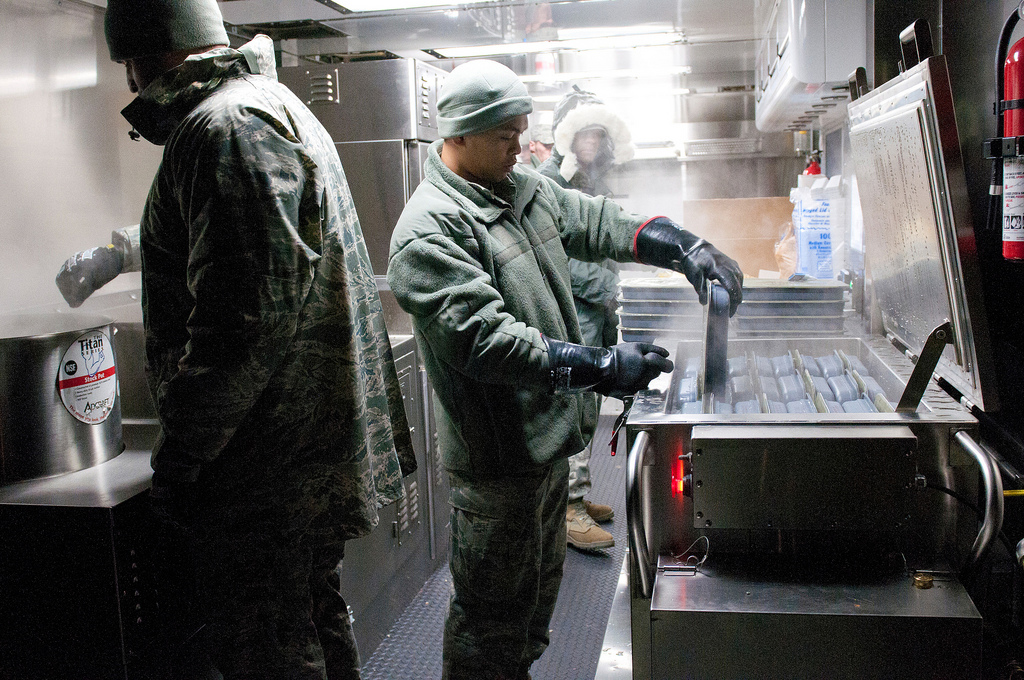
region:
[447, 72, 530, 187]
the head of a man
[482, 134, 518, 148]
the eyes of a man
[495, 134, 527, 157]
the nose of a man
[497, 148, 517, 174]
the mouth of a man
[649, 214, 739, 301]
the left hand of a man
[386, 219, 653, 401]
the right arm of a man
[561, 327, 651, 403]
the right hand of a man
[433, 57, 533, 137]
a man wearing a hat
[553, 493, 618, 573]
a man wearing brown boots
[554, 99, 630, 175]
a man wearing a coat hood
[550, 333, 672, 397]
a man wearing black gloves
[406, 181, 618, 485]
a man wearing a green sweetshirt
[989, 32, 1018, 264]
a red fire exstiguisher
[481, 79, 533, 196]
a man looking down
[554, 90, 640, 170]
white fake fur around a hood of a coat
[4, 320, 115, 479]
a silver metal pot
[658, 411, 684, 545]
Red light on front of machine.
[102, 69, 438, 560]
Large camoflauge jacket on the man.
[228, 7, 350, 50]
Ventilator on the top of the roof.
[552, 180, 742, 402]
Large black glove with a red stripe on the bottom.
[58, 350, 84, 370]
Black circle on front of the pot.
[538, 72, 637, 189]
Man with a large white hood around it.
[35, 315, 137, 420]
Red and white sticker on the side of pan.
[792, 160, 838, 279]
Clear bottle with blue writing and red top.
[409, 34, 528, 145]
Green skully on top of man's head.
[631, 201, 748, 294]
Large thick black and red glove on man's hand.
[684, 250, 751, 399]
Big black bowl getting sprayed.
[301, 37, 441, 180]
Large silver refrigerator in the corner.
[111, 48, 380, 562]
Large camouflage jacket on the man's body.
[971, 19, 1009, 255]
Red fire extinguisher on side of wall.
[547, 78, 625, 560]
Man standing in the back watching men cleaning.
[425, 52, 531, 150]
GRAY WINTER HAT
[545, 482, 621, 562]
USED BROWN ARMY BOOTS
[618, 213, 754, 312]
BLACK AND RED THERMAL GLOVES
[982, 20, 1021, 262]
LARGE RED FIRE EXTINGUISHER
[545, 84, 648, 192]
MAN WEARING WINTER HOOD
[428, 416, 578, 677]
CAMOFLAGE ARMY CARGO PANTS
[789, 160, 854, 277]
CLEAR PLASTIC CHEMICAL BOTTLES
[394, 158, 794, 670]
A man to the right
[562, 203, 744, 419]
The gloves on the man's hands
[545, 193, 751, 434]
A pair of gloves on the man's hand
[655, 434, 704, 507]
Red glow of a light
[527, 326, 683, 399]
Large black rubber glove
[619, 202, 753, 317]
Large black rubber glove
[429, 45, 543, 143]
A beanie on a man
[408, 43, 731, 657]
a person is standing up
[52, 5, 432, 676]
a person is standing up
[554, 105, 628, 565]
a person is standing up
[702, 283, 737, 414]
a plate made for dining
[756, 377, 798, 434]
a plate made for dining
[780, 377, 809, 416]
a plate made for dining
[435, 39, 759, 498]
a man in a freezer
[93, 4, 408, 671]
a man wearing a beanie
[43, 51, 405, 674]
a man wearing jacket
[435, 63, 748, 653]
a man wearing a jacket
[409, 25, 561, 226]
a man wearing a beanie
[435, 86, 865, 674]
a man wearing gloves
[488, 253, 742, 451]
a man wearing gloves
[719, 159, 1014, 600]
a freezer is open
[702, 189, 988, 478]
a metal freezer is open